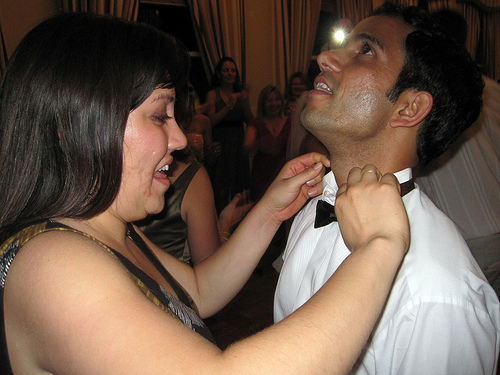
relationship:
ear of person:
[387, 89, 433, 128] [271, 3, 497, 369]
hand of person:
[333, 161, 410, 254] [2, 14, 398, 373]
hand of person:
[194, 150, 327, 319] [2, 14, 398, 373]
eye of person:
[149, 108, 172, 130] [2, 14, 398, 373]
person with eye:
[280, 34, 497, 369] [353, 30, 377, 62]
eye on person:
[353, 30, 377, 62] [280, 34, 497, 369]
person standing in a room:
[202, 54, 254, 204] [0, 12, 500, 375]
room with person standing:
[0, 12, 500, 375] [202, 54, 254, 204]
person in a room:
[271, 3, 497, 369] [207, 12, 287, 95]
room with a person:
[207, 12, 287, 95] [271, 3, 497, 369]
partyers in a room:
[241, 85, 292, 206] [0, 12, 500, 375]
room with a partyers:
[0, 12, 500, 375] [241, 85, 292, 206]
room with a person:
[0, 12, 500, 375] [271, 3, 497, 369]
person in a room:
[271, 3, 497, 369] [0, 12, 500, 375]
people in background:
[220, 50, 290, 123] [172, 9, 302, 69]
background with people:
[172, 9, 302, 69] [220, 50, 290, 123]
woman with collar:
[0, 17, 410, 373] [324, 176, 427, 199]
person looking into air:
[271, 3, 497, 369] [243, 13, 328, 30]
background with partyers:
[0, 9, 499, 154] [195, 45, 292, 143]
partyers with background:
[195, 45, 292, 143] [0, 9, 499, 154]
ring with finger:
[353, 162, 390, 197] [351, 153, 387, 193]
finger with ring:
[351, 153, 387, 193] [353, 162, 390, 197]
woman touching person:
[0, 9, 410, 372] [271, 3, 497, 369]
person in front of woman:
[271, 3, 497, 369] [0, 9, 410, 372]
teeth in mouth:
[153, 159, 171, 174] [150, 159, 180, 187]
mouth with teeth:
[150, 159, 180, 187] [153, 159, 171, 174]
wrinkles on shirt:
[430, 281, 497, 352] [431, 248, 484, 370]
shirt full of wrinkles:
[431, 248, 484, 370] [430, 281, 497, 352]